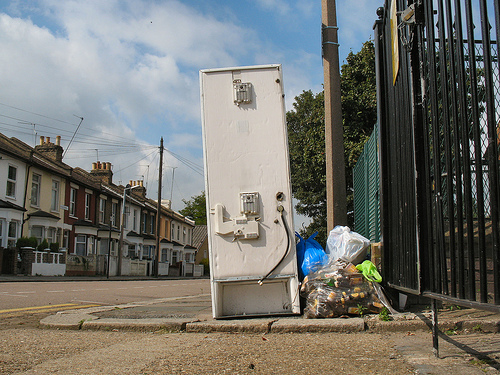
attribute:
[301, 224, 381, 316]
bag — trash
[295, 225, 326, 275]
bag — trash, blue, plastic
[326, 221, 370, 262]
bag — trash, plastic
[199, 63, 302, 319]
box — electrical, refrigerator, appliance, white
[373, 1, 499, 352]
fence — metal, black, gate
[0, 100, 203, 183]
wires — electrical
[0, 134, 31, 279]
home — two-story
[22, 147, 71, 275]
home — two-story, yellow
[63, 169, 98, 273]
home — two-story, red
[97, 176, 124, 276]
home — two-story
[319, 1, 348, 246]
pole — concrete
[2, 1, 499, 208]
sky — blue, cloudy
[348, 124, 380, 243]
fence — green, chainlink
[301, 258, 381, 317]
bag — plastic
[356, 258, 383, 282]
bag — plastic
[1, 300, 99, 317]
line — yellow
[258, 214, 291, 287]
cord — black